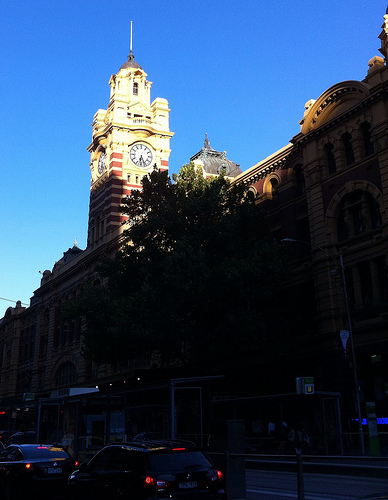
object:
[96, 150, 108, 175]
clock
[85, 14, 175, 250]
tower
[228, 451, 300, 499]
gate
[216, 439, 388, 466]
fence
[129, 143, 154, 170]
clock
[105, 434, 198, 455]
roof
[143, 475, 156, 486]
tail light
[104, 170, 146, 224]
car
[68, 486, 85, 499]
wheel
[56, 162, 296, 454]
trees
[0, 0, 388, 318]
sky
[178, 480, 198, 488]
license plate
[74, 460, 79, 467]
side mirror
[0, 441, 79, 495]
black car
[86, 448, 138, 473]
window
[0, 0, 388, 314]
view